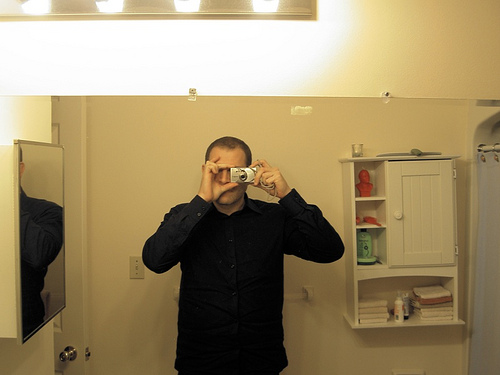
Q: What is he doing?
A: Taking a photo.